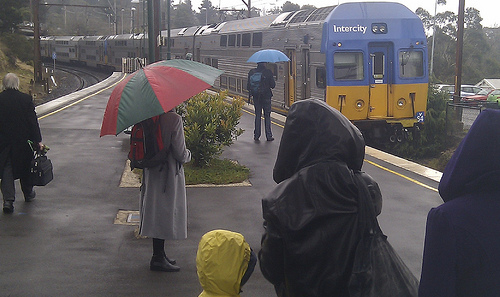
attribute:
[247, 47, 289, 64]
umbrella — blue 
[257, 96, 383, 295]
raincoat — black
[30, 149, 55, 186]
briefcase — black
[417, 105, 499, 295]
cloak — blue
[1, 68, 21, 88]
hair — gray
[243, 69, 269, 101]
backpack — blue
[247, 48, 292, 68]
umbrella — blue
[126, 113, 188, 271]
umbrella — red, green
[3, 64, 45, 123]
hair — grey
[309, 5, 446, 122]
train — blue, yellow, gray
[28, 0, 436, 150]
train — silver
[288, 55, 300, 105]
door — side, yellow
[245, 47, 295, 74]
umbrella — blue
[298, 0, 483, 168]
train — blue, yellow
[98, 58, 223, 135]
umbrella — red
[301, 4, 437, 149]
front — blue and yellow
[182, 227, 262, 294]
hood — yellow